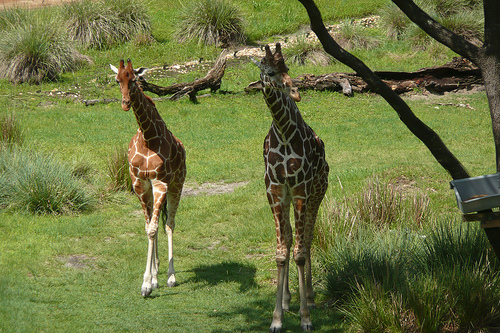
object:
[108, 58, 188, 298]
giraffe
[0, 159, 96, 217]
grass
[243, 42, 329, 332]
giraffe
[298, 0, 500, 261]
tree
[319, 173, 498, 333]
grass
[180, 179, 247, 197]
dirt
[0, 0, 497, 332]
field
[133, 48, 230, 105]
log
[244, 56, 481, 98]
log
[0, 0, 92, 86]
shrub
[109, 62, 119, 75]
ear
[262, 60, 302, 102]
face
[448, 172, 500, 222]
box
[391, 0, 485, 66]
branch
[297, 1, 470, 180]
branch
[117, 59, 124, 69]
horns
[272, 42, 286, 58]
horns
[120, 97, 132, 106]
nose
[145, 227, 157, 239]
knees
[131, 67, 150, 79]
ears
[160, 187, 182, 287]
legs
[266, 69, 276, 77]
eye